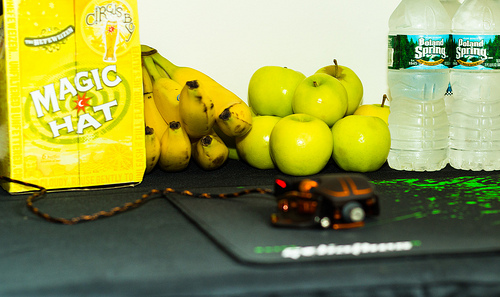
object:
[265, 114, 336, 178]
apple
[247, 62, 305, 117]
apple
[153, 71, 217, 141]
banana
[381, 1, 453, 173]
bottle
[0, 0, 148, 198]
carton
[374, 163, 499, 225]
splatter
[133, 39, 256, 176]
bunch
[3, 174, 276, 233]
string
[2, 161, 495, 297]
table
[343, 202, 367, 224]
button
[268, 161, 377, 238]
toy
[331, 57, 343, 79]
stem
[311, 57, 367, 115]
apple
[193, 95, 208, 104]
spot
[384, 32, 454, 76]
label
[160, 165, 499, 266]
pad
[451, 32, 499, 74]
label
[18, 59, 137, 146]
logo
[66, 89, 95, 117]
star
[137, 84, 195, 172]
banana